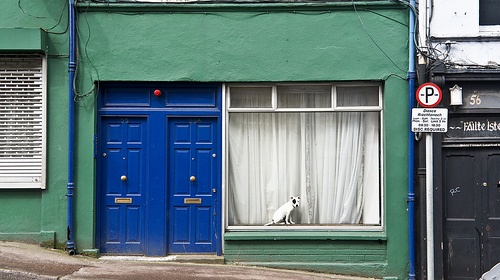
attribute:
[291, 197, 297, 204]
eye — black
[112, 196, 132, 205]
mail slot — gold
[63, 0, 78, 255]
pole — blue, metal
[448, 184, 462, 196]
graffiti patch — small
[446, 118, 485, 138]
sign — painted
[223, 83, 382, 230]
window — large, square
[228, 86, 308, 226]
curtain — white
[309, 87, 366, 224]
curtain — white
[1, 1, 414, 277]
wall — dark green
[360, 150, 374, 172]
handle — part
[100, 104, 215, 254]
doors — blue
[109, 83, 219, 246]
doors — blue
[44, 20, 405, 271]
building — green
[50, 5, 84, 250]
pipe — royal blue, royal drain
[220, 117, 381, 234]
window — large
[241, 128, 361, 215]
curtains — white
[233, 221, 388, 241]
sill — window, black and white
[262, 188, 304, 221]
dog — small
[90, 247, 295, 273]
pavement — uneven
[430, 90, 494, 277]
doors — black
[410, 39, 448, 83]
cords — electrical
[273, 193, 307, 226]
dog — white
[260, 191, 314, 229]
dog — white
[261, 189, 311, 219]
dog — white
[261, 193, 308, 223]
dog — white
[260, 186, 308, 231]
dog — white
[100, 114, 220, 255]
doors — blue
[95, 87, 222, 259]
doors — royal blue, blue